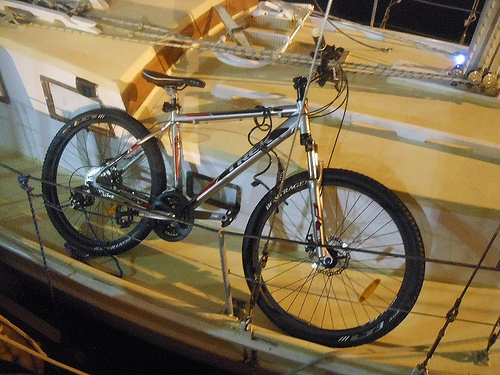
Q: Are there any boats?
A: Yes, there is a boat.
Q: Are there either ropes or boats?
A: Yes, there is a boat.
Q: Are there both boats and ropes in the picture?
A: Yes, there are both a boat and a rope.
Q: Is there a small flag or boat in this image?
A: Yes, there is a small boat.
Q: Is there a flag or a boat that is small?
A: Yes, the boat is small.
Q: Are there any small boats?
A: Yes, there is a small boat.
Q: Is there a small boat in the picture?
A: Yes, there is a small boat.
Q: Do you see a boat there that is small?
A: Yes, there is a boat that is small.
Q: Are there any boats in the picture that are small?
A: Yes, there is a boat that is small.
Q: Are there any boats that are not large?
A: Yes, there is a small boat.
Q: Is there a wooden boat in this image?
A: Yes, there is a wood boat.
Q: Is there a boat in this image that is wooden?
A: Yes, there is a boat that is wooden.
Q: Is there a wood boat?
A: Yes, there is a boat that is made of wood.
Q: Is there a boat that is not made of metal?
A: Yes, there is a boat that is made of wood.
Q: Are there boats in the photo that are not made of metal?
A: Yes, there is a boat that is made of wood.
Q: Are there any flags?
A: No, there are no flags.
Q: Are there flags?
A: No, there are no flags.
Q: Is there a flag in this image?
A: No, there are no flags.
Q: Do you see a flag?
A: No, there are no flags.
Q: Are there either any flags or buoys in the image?
A: No, there are no flags or buoys.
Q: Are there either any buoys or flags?
A: No, there are no flags or buoys.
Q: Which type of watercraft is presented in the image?
A: The watercraft is a boat.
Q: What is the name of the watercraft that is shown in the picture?
A: The watercraft is a boat.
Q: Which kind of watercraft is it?
A: The watercraft is a boat.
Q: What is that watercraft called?
A: This is a boat.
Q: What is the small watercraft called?
A: The watercraft is a boat.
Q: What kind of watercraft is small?
A: The watercraft is a boat.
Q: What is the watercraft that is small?
A: The watercraft is a boat.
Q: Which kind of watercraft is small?
A: The watercraft is a boat.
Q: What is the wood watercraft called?
A: The watercraft is a boat.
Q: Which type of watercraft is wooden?
A: The watercraft is a boat.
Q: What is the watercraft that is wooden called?
A: The watercraft is a boat.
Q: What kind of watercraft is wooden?
A: The watercraft is a boat.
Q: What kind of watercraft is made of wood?
A: The watercraft is a boat.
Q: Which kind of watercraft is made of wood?
A: The watercraft is a boat.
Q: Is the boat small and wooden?
A: Yes, the boat is small and wooden.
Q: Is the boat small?
A: Yes, the boat is small.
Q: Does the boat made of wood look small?
A: Yes, the boat is small.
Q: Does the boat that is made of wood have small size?
A: Yes, the boat is small.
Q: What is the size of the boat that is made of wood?
A: The boat is small.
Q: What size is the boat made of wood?
A: The boat is small.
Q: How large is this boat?
A: The boat is small.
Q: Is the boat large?
A: No, the boat is small.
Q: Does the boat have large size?
A: No, the boat is small.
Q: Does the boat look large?
A: No, the boat is small.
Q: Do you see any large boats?
A: No, there is a boat but it is small.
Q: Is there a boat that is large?
A: No, there is a boat but it is small.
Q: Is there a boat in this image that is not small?
A: No, there is a boat but it is small.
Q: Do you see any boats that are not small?
A: No, there is a boat but it is small.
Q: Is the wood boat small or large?
A: The boat is small.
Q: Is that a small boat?
A: Yes, that is a small boat.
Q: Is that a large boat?
A: No, that is a small boat.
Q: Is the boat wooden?
A: Yes, the boat is wooden.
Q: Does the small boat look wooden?
A: Yes, the boat is wooden.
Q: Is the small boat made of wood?
A: Yes, the boat is made of wood.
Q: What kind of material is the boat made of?
A: The boat is made of wood.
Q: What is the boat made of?
A: The boat is made of wood.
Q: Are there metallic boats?
A: No, there is a boat but it is wooden.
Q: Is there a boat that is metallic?
A: No, there is a boat but it is wooden.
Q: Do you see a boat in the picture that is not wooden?
A: No, there is a boat but it is wooden.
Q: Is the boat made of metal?
A: No, the boat is made of wood.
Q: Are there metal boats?
A: No, there is a boat but it is made of wood.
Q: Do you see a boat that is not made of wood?
A: No, there is a boat but it is made of wood.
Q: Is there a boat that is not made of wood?
A: No, there is a boat but it is made of wood.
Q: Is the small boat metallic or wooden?
A: The boat is wooden.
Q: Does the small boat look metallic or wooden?
A: The boat is wooden.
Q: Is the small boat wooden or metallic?
A: The boat is wooden.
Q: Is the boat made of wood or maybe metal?
A: The boat is made of wood.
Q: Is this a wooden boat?
A: Yes, this is a wooden boat.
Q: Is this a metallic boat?
A: No, this is a wooden boat.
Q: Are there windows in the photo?
A: Yes, there is a window.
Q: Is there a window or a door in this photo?
A: Yes, there is a window.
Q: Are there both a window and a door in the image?
A: No, there is a window but no doors.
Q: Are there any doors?
A: No, there are no doors.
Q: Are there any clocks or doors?
A: No, there are no doors or clocks.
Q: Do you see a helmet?
A: No, there are no helmets.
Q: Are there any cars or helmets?
A: No, there are no helmets or cars.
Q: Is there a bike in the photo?
A: Yes, there is a bike.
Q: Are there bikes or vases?
A: Yes, there is a bike.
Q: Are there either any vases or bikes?
A: Yes, there is a bike.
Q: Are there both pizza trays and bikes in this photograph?
A: No, there is a bike but no pizza trays.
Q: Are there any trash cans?
A: No, there are no trash cans.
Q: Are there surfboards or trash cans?
A: No, there are no trash cans or surfboards.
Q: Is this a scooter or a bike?
A: This is a bike.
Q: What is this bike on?
A: The bike is on the boat.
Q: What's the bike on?
A: The bike is on the boat.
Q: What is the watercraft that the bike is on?
A: The watercraft is a boat.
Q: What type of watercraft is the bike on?
A: The bike is on the boat.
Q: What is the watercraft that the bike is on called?
A: The watercraft is a boat.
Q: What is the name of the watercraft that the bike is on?
A: The watercraft is a boat.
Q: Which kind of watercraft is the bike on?
A: The bike is on the boat.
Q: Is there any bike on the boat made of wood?
A: Yes, there is a bike on the boat.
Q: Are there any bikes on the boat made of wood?
A: Yes, there is a bike on the boat.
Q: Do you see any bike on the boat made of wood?
A: Yes, there is a bike on the boat.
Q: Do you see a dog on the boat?
A: No, there is a bike on the boat.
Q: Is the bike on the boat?
A: Yes, the bike is on the boat.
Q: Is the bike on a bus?
A: No, the bike is on the boat.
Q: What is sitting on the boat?
A: The bike is sitting on the boat.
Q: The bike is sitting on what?
A: The bike is sitting on the boat.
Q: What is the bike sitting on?
A: The bike is sitting on the boat.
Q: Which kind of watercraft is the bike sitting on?
A: The bike is sitting on the boat.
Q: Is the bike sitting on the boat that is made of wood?
A: Yes, the bike is sitting on the boat.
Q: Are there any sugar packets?
A: No, there are no sugar packets.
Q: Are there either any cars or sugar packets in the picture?
A: No, there are no sugar packets or cars.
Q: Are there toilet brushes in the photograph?
A: No, there are no toilet brushes.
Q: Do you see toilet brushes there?
A: No, there are no toilet brushes.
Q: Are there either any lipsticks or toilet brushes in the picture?
A: No, there are no toilet brushes or lipsticks.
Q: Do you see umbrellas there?
A: No, there are no umbrellas.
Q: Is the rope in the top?
A: Yes, the rope is in the top of the image.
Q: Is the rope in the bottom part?
A: No, the rope is in the top of the image.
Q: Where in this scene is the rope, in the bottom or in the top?
A: The rope is in the top of the image.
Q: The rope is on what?
A: The rope is on the boat.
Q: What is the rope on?
A: The rope is on the boat.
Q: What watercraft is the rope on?
A: The rope is on the boat.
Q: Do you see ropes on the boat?
A: Yes, there is a rope on the boat.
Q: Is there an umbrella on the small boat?
A: No, there is a rope on the boat.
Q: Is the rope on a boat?
A: Yes, the rope is on a boat.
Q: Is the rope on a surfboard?
A: No, the rope is on a boat.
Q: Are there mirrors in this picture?
A: No, there are no mirrors.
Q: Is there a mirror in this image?
A: No, there are no mirrors.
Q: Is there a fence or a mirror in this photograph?
A: No, there are no mirrors or fences.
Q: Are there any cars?
A: No, there are no cars.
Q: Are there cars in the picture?
A: No, there are no cars.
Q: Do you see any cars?
A: No, there are no cars.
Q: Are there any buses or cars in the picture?
A: No, there are no cars or buses.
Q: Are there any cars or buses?
A: No, there are no cars or buses.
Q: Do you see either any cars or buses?
A: No, there are no cars or buses.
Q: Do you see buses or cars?
A: No, there are no cars or buses.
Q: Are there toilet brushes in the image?
A: No, there are no toilet brushes.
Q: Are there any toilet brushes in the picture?
A: No, there are no toilet brushes.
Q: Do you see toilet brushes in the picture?
A: No, there are no toilet brushes.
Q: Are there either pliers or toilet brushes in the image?
A: No, there are no toilet brushes or pliers.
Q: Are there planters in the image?
A: No, there are no planters.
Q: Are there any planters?
A: No, there are no planters.